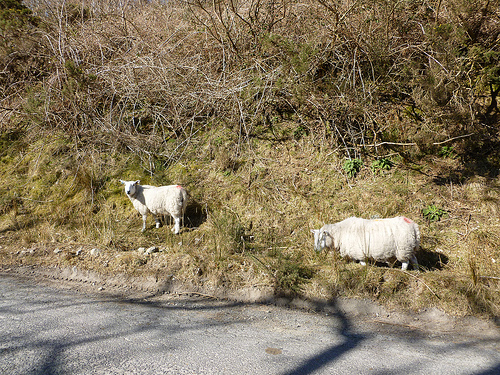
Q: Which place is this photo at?
A: It is at the road.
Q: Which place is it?
A: It is a road.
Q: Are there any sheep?
A: Yes, there is a sheep.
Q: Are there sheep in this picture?
A: Yes, there is a sheep.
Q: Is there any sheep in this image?
A: Yes, there is a sheep.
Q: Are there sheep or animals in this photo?
A: Yes, there is a sheep.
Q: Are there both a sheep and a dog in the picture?
A: No, there is a sheep but no dogs.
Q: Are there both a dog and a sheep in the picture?
A: No, there is a sheep but no dogs.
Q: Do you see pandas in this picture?
A: No, there are no pandas.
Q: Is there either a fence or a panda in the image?
A: No, there are no pandas or fences.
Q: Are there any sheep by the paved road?
A: Yes, there is a sheep by the road.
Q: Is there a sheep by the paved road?
A: Yes, there is a sheep by the road.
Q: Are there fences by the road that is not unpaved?
A: No, there is a sheep by the road.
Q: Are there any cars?
A: No, there are no cars.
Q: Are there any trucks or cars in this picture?
A: No, there are no cars or trucks.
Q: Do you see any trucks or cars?
A: No, there are no cars or trucks.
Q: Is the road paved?
A: Yes, the road is paved.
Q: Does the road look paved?
A: Yes, the road is paved.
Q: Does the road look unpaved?
A: No, the road is paved.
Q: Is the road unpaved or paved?
A: The road is paved.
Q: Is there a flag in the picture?
A: No, there are no flags.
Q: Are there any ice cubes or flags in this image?
A: No, there are no flags or ice cubes.